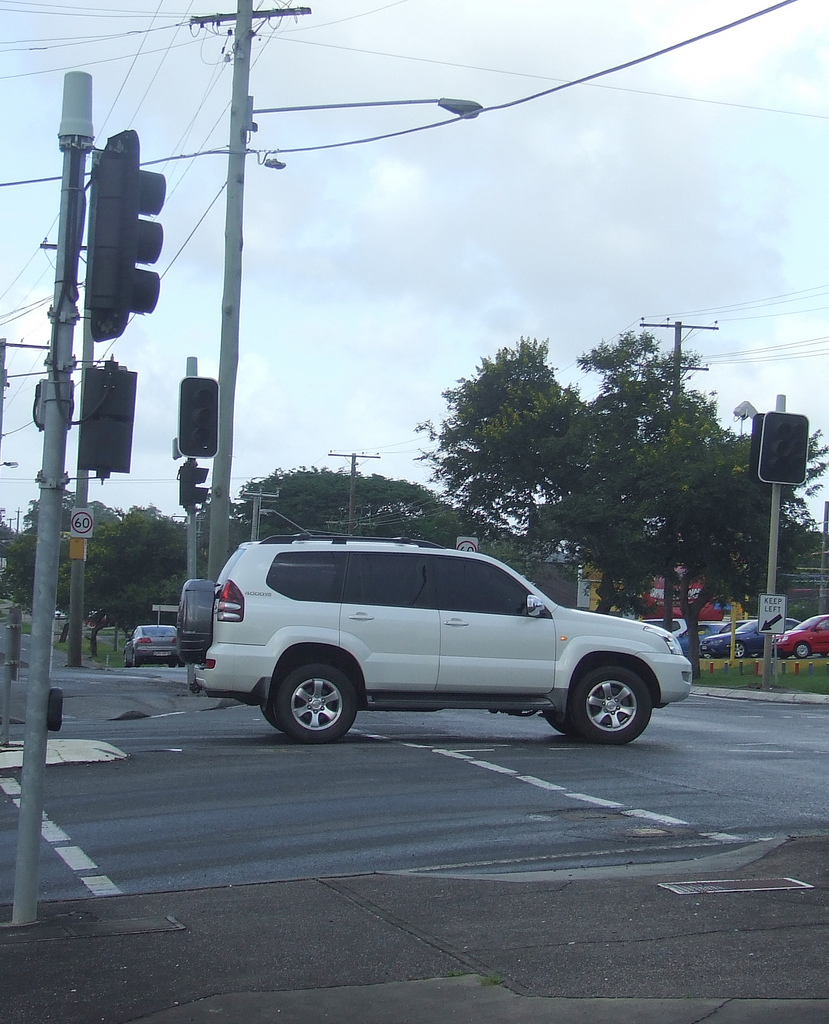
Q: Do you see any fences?
A: No, there are no fences.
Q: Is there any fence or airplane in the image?
A: No, there are no fences or airplanes.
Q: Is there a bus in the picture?
A: No, there are no buses.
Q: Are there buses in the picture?
A: No, there are no buses.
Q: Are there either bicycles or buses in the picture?
A: No, there are no buses or bicycles.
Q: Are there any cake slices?
A: No, there are no cake slices.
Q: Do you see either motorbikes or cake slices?
A: No, there are no cake slices or motorbikes.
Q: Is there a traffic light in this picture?
A: Yes, there is a traffic light.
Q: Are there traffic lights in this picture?
A: Yes, there is a traffic light.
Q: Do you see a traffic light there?
A: Yes, there is a traffic light.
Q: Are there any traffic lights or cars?
A: Yes, there is a traffic light.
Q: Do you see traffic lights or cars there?
A: Yes, there is a traffic light.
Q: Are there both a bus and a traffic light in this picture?
A: No, there is a traffic light but no buses.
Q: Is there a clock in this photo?
A: No, there are no clocks.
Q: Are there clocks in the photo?
A: No, there are no clocks.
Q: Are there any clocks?
A: No, there are no clocks.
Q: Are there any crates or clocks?
A: No, there are no clocks or crates.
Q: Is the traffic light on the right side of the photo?
A: Yes, the traffic light is on the right of the image.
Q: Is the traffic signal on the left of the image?
A: No, the traffic signal is on the right of the image.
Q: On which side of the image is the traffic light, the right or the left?
A: The traffic light is on the right of the image.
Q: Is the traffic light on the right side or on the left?
A: The traffic light is on the right of the image.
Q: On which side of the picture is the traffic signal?
A: The traffic signal is on the right of the image.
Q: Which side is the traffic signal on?
A: The traffic signal is on the right of the image.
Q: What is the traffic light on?
A: The traffic light is on the pole.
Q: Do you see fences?
A: No, there are no fences.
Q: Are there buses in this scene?
A: No, there are no buses.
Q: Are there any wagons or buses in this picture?
A: No, there are no buses or wagons.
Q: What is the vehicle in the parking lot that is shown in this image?
A: The vehicle is a car.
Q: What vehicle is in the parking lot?
A: The vehicle is a car.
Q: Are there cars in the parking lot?
A: Yes, there is a car in the parking lot.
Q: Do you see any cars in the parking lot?
A: Yes, there is a car in the parking lot.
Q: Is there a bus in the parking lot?
A: No, there is a car in the parking lot.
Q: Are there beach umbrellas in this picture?
A: No, there are no beach umbrellas.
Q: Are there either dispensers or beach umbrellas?
A: No, there are no beach umbrellas or dispensers.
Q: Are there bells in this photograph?
A: No, there are no bells.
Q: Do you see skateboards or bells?
A: No, there are no bells or skateboards.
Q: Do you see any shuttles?
A: No, there are no shuttles.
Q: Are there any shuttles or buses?
A: No, there are no shuttles or buses.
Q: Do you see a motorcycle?
A: No, there are no motorcycles.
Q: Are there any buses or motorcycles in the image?
A: No, there are no motorcycles or buses.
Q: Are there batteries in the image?
A: No, there are no batteries.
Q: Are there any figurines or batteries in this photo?
A: No, there are no batteries or figurines.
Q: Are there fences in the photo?
A: No, there are no fences.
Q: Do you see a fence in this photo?
A: No, there are no fences.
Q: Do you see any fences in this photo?
A: No, there are no fences.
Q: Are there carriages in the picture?
A: No, there are no carriages.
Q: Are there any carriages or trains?
A: No, there are no carriages or trains.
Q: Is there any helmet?
A: No, there are no helmets.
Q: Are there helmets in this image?
A: No, there are no helmets.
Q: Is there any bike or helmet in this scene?
A: No, there are no helmets or bikes.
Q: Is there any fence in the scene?
A: No, there are no fences.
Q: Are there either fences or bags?
A: No, there are no fences or bags.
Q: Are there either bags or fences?
A: No, there are no fences or bags.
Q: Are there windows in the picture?
A: Yes, there is a window.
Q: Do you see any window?
A: Yes, there is a window.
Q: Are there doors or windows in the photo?
A: Yes, there is a window.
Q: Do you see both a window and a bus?
A: No, there is a window but no buses.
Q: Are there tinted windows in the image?
A: Yes, there is a tinted window.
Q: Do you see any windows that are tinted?
A: Yes, there is a window that is tinted.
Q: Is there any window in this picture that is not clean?
A: Yes, there is a tinted window.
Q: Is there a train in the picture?
A: No, there are no trains.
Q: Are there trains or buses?
A: No, there are no trains or buses.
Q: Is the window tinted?
A: Yes, the window is tinted.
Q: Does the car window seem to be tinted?
A: Yes, the window is tinted.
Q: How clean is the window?
A: The window is tinted.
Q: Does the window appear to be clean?
A: No, the window is tinted.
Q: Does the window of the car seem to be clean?
A: No, the window is tinted.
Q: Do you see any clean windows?
A: No, there is a window but it is tinted.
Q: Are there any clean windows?
A: No, there is a window but it is tinted.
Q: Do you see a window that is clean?
A: No, there is a window but it is tinted.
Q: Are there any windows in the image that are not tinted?
A: No, there is a window but it is tinted.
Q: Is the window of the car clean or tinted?
A: The window is tinted.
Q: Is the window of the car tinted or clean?
A: The window is tinted.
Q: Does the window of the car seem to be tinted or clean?
A: The window is tinted.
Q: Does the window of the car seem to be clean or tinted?
A: The window is tinted.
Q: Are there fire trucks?
A: No, there are no fire trucks.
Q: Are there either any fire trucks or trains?
A: No, there are no fire trucks or trains.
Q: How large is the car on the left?
A: The car is small.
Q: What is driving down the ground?
A: The car is driving down the ground.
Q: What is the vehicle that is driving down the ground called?
A: The vehicle is a car.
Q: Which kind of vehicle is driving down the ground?
A: The vehicle is a car.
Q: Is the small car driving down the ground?
A: Yes, the car is driving down the ground.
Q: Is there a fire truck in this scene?
A: No, there are no fire trucks.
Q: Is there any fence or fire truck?
A: No, there are no fire trucks or fences.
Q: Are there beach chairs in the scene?
A: No, there are no beach chairs.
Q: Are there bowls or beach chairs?
A: No, there are no beach chairs or bowls.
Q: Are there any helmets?
A: No, there are no helmets.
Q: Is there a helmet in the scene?
A: No, there are no helmets.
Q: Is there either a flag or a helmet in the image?
A: No, there are no helmets or flags.